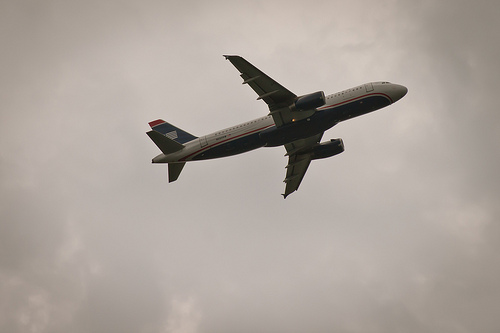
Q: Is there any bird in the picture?
A: No, there are no birds.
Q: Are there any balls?
A: No, there are no balls.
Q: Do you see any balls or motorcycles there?
A: No, there are no balls or motorcycles.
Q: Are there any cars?
A: No, there are no cars.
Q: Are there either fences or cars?
A: No, there are no cars or fences.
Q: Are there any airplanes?
A: Yes, there is an airplane.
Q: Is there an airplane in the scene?
A: Yes, there is an airplane.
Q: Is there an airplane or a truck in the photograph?
A: Yes, there is an airplane.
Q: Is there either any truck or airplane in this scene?
A: Yes, there is an airplane.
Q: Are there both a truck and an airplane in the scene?
A: No, there is an airplane but no trucks.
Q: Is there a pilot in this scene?
A: No, there are no pilots.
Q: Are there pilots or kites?
A: No, there are no pilots or kites.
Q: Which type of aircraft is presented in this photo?
A: The aircraft is an airplane.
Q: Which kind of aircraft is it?
A: The aircraft is an airplane.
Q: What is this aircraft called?
A: This is an airplane.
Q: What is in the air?
A: The airplane is in the air.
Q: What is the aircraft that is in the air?
A: The aircraft is an airplane.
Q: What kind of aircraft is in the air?
A: The aircraft is an airplane.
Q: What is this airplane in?
A: The airplane is in the air.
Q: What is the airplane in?
A: The airplane is in the air.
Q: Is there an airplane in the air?
A: Yes, there is an airplane in the air.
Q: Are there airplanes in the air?
A: Yes, there is an airplane in the air.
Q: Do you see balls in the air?
A: No, there is an airplane in the air.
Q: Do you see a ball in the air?
A: No, there is an airplane in the air.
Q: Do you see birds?
A: No, there are no birds.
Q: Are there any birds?
A: No, there are no birds.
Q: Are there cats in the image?
A: No, there are no cats.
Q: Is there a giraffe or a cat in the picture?
A: No, there are no cats or giraffes.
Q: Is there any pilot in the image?
A: No, there are no pilots.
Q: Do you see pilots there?
A: No, there are no pilots.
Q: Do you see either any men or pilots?
A: No, there are no pilots or men.